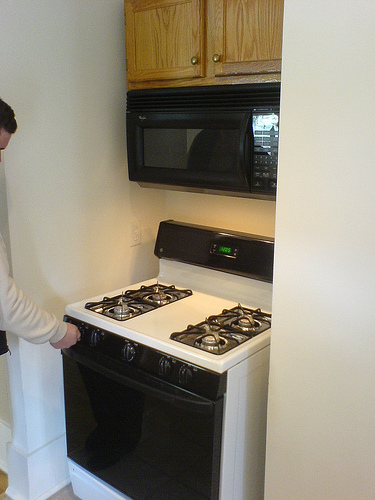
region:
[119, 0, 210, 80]
a brown cabinet door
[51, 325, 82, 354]
the hand of a man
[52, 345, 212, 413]
a black oven handle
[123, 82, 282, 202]
an over the counter microwave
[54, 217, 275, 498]
a black and white oven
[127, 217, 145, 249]
a white wall outlet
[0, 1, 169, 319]
part of a white wall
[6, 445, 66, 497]
a piece of white floor trim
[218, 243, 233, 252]
a green clock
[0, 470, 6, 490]
a small section of hardwood floor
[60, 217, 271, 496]
White and black stove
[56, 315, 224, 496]
Stove's black door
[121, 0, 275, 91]
Two wood cabinet doors over stove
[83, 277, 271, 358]
Stove's four burners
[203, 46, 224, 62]
Knob on left cabinet door over stove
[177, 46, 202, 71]
Right knob on wood cabinet door over stove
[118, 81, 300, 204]
Microwave over white stove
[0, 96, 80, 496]
Man operating white stove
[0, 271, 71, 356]
Right sleeve of man operating stove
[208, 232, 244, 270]
Clock in top part of white stove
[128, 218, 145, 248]
an electric wall outlet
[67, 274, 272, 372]
a gas range top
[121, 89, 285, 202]
under cabinet mounted microwave oven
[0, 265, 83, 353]
sweatered arm turning control knob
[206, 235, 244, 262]
time display on stove top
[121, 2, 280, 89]
double door blond oak cabinet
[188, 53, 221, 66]
brass knobs on cabinet doors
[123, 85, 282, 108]
vent for microwave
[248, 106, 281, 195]
daylight from window reflected off microwave control panel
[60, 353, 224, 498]
reflection of feet standing on linoleum floor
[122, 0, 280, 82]
A brown cabinet with gold knobs.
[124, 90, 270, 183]
A black microwave with multiple buttons.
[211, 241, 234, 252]
A clock that is too blurry to read.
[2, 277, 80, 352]
A person using the dial to turn on the stove.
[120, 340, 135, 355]
A black stove dial.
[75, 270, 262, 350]
A four burner stove top.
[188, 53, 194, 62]
A gold knob for a cabinet.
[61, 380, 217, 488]
A black oven window.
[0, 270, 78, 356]
A person wearing a cream colored shirt.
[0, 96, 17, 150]
A part of a persons head with brown hair.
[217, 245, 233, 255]
Electronic clock on the oven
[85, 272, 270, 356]
Burners on the stove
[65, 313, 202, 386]
Black dials controlling the oven and stove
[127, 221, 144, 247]
White socket outlet on the wall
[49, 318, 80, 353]
A hand turning the nob on the oven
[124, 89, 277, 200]
Black microwave oven mounted on the wall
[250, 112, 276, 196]
Control panel for the microwave oven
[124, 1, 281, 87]
Wooden cabinets mounted on the wall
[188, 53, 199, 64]
The knob handle of the cabinet door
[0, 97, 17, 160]
Portion of the person's head who is operating the oven